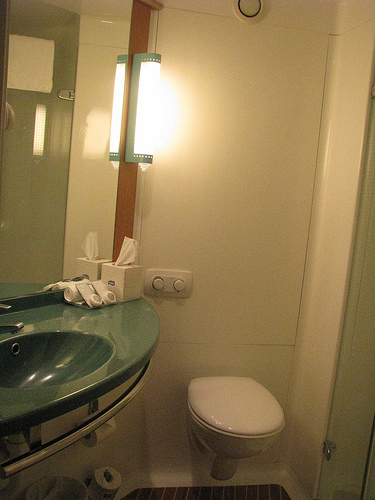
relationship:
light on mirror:
[127, 57, 172, 166] [9, 15, 124, 276]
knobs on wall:
[64, 62, 89, 182] [92, 1, 291, 330]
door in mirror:
[14, 12, 67, 299] [9, 15, 124, 276]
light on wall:
[127, 57, 172, 166] [92, 1, 291, 330]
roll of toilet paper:
[89, 455, 128, 491] [91, 424, 133, 449]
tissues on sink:
[112, 246, 155, 319] [9, 298, 155, 420]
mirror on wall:
[9, 15, 124, 276] [92, 1, 291, 330]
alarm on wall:
[236, 1, 281, 23] [92, 1, 291, 330]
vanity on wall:
[73, 25, 201, 238] [92, 1, 291, 330]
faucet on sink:
[9, 302, 16, 345] [9, 298, 155, 420]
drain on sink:
[16, 347, 39, 370] [9, 298, 155, 420]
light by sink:
[127, 57, 172, 166] [9, 298, 155, 420]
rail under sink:
[117, 376, 180, 399] [9, 298, 155, 420]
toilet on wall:
[192, 381, 281, 459] [142, 51, 292, 453]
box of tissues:
[100, 261, 145, 302] [112, 246, 155, 319]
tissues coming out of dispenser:
[112, 246, 155, 319] [101, 263, 148, 305]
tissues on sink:
[112, 246, 155, 319] [3, 299, 165, 432]